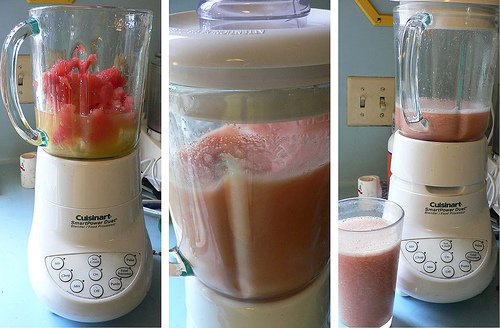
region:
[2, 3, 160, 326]
fruit in a blender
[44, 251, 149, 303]
buttons on a blender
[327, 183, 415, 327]
shake in a glass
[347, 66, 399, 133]
switch outlet on wall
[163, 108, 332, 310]
pureed fruit in blender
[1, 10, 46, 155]
handle of a blender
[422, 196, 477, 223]
Cuisinart name on blender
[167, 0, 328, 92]
lid cover on a blender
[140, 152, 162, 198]
white plug to a blender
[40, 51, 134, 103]
watermelon in a blender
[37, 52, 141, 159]
unblended fruit in left blender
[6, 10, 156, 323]
blender on the left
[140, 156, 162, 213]
blender power cord in left picture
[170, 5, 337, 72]
white lid on blender in center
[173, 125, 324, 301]
smoothie being mixed in center blender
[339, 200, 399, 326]
glass of watermelon smoothie on right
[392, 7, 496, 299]
right most blender half-full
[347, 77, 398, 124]
two light switches on well, one on one off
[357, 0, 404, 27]
yellow picture frame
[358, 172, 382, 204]
white mug in background of right blender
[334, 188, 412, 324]
glass with blended beverage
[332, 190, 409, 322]
glass with nice blended beverage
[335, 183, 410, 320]
glass with tasty blended beverage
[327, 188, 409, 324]
glass with delicious blended beverage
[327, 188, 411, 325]
glass with cool blended beverage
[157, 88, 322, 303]
food being blended in blender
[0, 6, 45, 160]
handle to a blender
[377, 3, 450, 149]
glass handle to blender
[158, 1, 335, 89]
lid to a blender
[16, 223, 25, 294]
shiny blue surface on the counter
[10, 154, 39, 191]
small white cup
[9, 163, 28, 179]
red line on white cup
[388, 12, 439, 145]
clear handle on white blender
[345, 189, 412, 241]
lid on clear drinking glass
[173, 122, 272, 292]
groove in the side of the blender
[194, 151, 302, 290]
pink liquid in clear blender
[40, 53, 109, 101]
watermelon chunks in blender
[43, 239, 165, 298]
white round buttons on blender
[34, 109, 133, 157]
small chunks of yellow pineapple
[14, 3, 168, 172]
glass container of fruit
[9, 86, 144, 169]
liquid in glass container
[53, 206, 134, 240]
black writing on white background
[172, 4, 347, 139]
white and glass top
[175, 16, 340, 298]
container with lid on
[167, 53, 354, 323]
strawberry smoothie in container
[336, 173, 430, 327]
glass of strawberry smoothie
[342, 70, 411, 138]
light switch on wall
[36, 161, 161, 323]
buttons on the blender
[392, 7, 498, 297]
blender with glass container